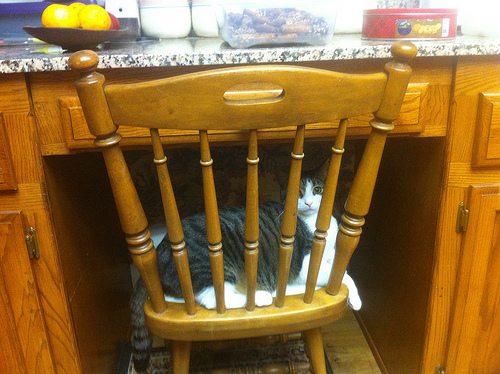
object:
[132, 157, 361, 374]
cat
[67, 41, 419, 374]
chair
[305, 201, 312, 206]
white nose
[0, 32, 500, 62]
desk top area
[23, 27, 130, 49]
bowl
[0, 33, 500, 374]
counter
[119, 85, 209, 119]
wood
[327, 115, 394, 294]
dowels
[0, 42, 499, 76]
shelf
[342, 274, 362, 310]
white front leg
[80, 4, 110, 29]
lemon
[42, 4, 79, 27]
lemon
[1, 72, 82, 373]
cupboard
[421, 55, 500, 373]
cupboard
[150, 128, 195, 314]
baluster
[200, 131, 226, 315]
baluster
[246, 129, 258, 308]
baluster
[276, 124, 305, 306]
baluster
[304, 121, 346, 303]
baluster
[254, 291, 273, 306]
white paw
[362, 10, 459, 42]
tin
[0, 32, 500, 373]
desk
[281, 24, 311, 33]
cookie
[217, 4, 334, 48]
plastic container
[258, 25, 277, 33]
cookie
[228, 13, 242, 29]
cookie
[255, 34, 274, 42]
cookie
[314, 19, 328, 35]
cookie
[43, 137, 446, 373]
under a desk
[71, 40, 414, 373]
back of chair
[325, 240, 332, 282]
solid white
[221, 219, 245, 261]
black stripes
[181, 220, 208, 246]
grey stripes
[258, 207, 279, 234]
black stripes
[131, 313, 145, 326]
grey stripes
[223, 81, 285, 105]
cutout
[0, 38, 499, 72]
countertop edge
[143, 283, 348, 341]
chair edge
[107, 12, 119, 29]
apple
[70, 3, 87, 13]
orange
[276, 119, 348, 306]
two dowels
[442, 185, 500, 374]
cabinet door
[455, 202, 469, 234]
hinge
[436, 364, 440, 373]
hinge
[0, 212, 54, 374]
cabinet door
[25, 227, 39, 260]
hinge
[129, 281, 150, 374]
tail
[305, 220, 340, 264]
white chest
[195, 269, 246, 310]
white legs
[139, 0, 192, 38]
jar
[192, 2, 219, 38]
jar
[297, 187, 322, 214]
white face